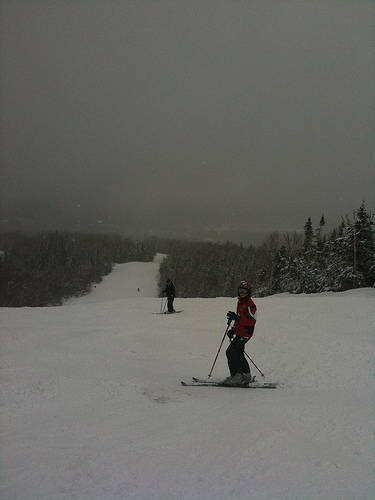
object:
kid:
[226, 281, 257, 384]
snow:
[0, 253, 375, 500]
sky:
[212, 85, 291, 187]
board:
[181, 377, 277, 389]